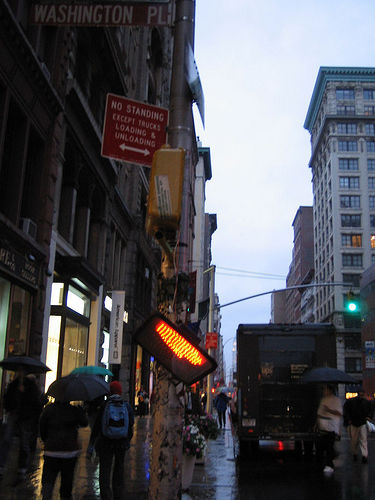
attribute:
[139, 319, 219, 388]
crosswalk sign — upside down, orange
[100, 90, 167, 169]
sign — red, white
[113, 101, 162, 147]
letters — white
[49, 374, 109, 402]
umbrella — black, dark, open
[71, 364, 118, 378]
umbrella — green, blue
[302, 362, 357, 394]
umbrella — black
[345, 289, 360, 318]
traffic light — green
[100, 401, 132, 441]
backpack — blue, black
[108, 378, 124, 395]
hat — red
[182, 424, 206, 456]
flowers — white, pink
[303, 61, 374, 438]
building — tall, tan, white, grey, large, beige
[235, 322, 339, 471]
vehicle — large, black, ups truck, dark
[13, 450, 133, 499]
pavement — wet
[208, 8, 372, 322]
sky — grey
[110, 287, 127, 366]
banner — white, black